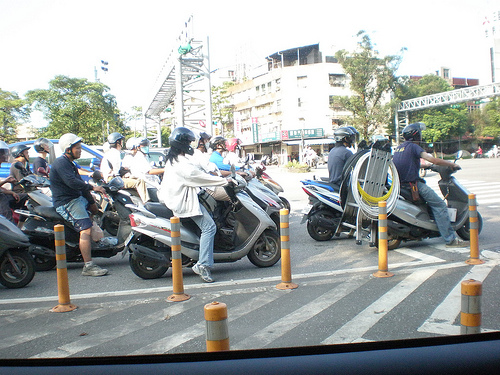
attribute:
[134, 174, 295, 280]
motorcycle — red white, blue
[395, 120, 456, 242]
man — sitting, here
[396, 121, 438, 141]
helmet — black, protective motorcycle, protective, here, on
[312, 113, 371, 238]
motorcyclist — stopped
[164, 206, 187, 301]
pole — orange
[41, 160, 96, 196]
sweatshirt — black, blue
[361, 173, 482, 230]
motorcycle — towing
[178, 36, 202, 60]
rag — blue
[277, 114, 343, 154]
sign — green, red, blue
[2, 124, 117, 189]
automobile — blue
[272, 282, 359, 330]
line — white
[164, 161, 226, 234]
jacket — white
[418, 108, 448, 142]
bush — green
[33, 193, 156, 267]
scooter — grey, here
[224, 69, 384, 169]
building — corner , here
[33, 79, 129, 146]
tree — back round 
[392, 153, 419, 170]
shirt — blue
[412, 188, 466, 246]
jeans — worn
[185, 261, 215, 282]
sneakers — grey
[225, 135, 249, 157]
helmet — pink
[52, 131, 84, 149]
helmet — white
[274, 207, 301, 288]
pylon — white, row